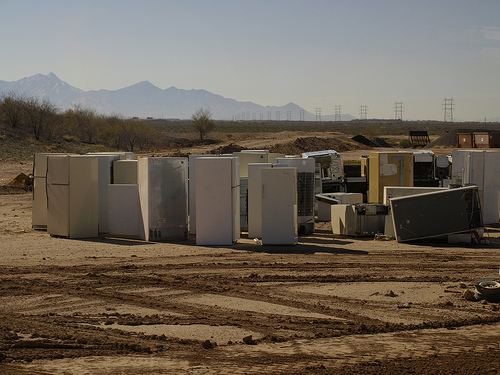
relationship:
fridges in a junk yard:
[26, 138, 499, 244] [8, 129, 500, 370]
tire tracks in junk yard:
[4, 250, 491, 374] [8, 129, 500, 370]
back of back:
[388, 186, 479, 244] [390, 186, 478, 243]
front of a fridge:
[47, 160, 69, 236] [45, 154, 101, 238]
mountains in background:
[3, 72, 366, 122] [2, 3, 500, 130]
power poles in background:
[247, 98, 459, 122] [2, 3, 500, 130]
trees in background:
[5, 93, 225, 154] [2, 3, 500, 130]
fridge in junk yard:
[196, 157, 242, 245] [8, 129, 500, 370]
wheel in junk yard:
[468, 277, 500, 299] [8, 129, 500, 370]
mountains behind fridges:
[3, 72, 366, 122] [26, 138, 499, 244]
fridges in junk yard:
[26, 138, 499, 244] [8, 129, 500, 370]